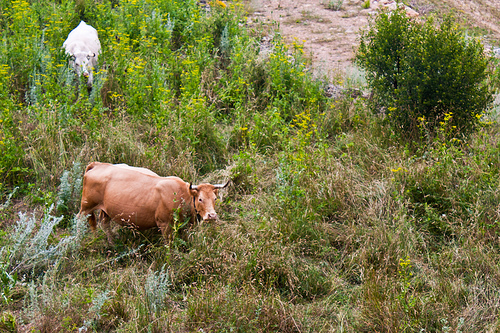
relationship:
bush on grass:
[356, 4, 498, 143] [0, 115, 495, 331]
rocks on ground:
[305, 23, 334, 45] [1, 0, 496, 328]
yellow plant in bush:
[438, 108, 450, 130] [353, 7, 498, 122]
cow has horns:
[75, 160, 243, 243] [186, 174, 235, 194]